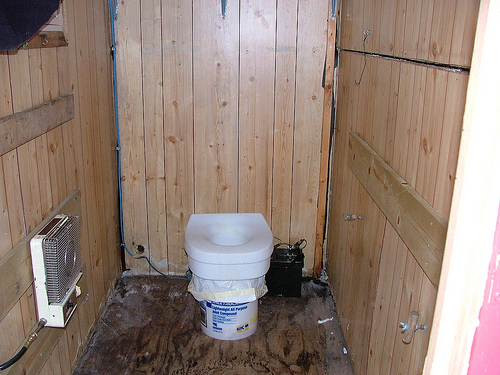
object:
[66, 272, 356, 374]
floor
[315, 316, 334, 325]
paper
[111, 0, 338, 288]
wall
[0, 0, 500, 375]
outhouse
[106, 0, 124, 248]
cord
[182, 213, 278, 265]
seat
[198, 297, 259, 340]
bucket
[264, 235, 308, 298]
battery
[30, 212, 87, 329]
heater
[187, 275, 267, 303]
bag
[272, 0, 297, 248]
panel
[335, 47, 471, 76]
pipe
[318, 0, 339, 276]
wire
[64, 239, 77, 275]
fan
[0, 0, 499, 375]
room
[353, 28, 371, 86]
hook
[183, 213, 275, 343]
toilet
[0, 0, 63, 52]
window